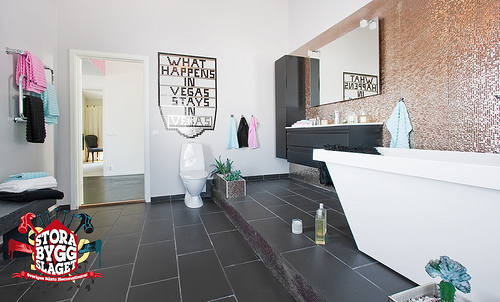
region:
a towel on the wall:
[383, 95, 415, 150]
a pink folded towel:
[10, 50, 50, 94]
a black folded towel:
[14, 92, 50, 145]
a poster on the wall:
[155, 45, 223, 140]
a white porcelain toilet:
[176, 136, 214, 216]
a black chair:
[78, 129, 108, 165]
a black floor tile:
[124, 235, 181, 292]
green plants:
[206, 152, 240, 178]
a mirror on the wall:
[301, 12, 389, 111]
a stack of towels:
[0, 166, 70, 210]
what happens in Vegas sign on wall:
[151, 44, 231, 145]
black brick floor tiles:
[133, 224, 239, 299]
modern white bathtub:
[311, 128, 493, 281]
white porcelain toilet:
[166, 140, 212, 217]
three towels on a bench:
[3, 165, 63, 206]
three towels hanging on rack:
[1, 32, 74, 156]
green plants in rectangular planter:
[206, 154, 252, 221]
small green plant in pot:
[403, 252, 491, 297]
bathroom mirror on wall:
[304, 12, 386, 112]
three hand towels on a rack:
[223, 110, 267, 157]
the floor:
[160, 209, 214, 290]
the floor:
[106, 183, 208, 288]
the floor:
[118, 229, 171, 276]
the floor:
[143, 196, 237, 288]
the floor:
[114, 225, 194, 298]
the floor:
[154, 248, 211, 300]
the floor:
[105, 240, 175, 287]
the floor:
[198, 294, 202, 297]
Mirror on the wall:
[308, 16, 383, 106]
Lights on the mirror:
[305, 17, 373, 59]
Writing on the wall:
[157, 50, 218, 138]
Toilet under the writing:
[177, 140, 209, 206]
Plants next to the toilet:
[210, 153, 245, 198]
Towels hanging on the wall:
[225, 110, 258, 149]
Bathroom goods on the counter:
[290, 105, 371, 127]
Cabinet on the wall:
[273, 55, 303, 159]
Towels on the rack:
[15, 47, 60, 143]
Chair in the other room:
[84, 131, 103, 162]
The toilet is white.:
[160, 136, 210, 221]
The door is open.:
[45, 33, 166, 220]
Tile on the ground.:
[130, 212, 222, 292]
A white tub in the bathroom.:
[303, 118, 498, 278]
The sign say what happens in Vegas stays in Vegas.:
[147, 33, 228, 139]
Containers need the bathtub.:
[275, 190, 332, 258]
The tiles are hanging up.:
[13, 43, 74, 149]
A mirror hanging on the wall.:
[291, 13, 401, 105]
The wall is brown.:
[396, 21, 484, 88]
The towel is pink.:
[14, 48, 49, 92]